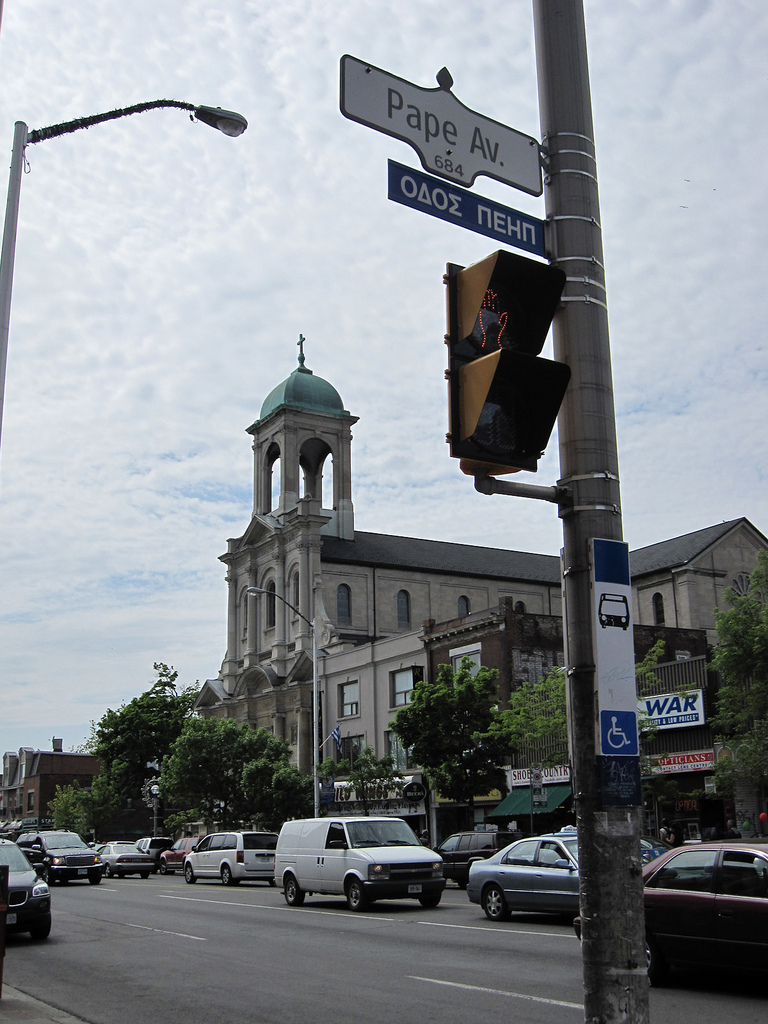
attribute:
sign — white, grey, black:
[331, 50, 548, 195]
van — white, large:
[269, 807, 450, 913]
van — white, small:
[166, 810, 272, 893]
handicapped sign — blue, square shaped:
[593, 709, 646, 759]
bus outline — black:
[596, 589, 637, 636]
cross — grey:
[289, 332, 322, 376]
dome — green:
[253, 369, 350, 433]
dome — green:
[258, 369, 347, 430]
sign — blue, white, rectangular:
[378, 165, 562, 248]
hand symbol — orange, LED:
[462, 285, 523, 363]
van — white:
[261, 813, 448, 916]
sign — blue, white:
[588, 525, 649, 754]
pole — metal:
[526, 9, 662, 1022]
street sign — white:
[328, 50, 545, 200]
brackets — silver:
[546, 159, 604, 189]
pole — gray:
[540, 11, 660, 1021]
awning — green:
[484, 779, 576, 820]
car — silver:
[465, 821, 635, 924]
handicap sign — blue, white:
[602, 698, 646, 748]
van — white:
[275, 804, 448, 907]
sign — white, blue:
[638, 682, 707, 740]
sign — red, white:
[632, 735, 721, 782]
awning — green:
[479, 785, 582, 821]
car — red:
[568, 824, 766, 991]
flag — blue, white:
[322, 718, 361, 771]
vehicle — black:
[10, 807, 104, 882]